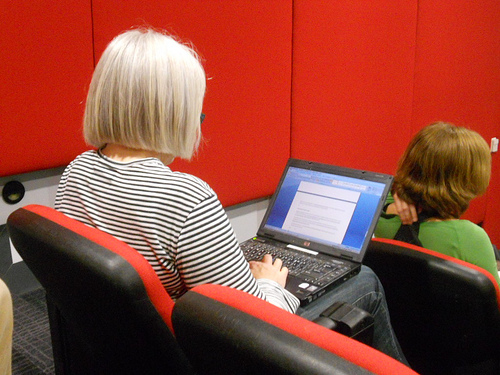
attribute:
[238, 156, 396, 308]
computer — black, opened, a laptop, on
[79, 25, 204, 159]
hair — gray, white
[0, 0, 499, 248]
wall — orange, red, padded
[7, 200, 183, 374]
seat — black, orange, red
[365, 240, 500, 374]
back — black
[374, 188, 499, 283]
shirt — green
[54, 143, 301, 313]
shirt — black, striped, white, long sleeved, stripped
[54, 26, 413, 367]
woman — sitting down, sitting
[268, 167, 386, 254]
screen — on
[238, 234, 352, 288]
keyboard — of laptop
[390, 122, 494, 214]
hair — red, blonde, brown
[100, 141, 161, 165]
neck — of woman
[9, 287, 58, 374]
floor — of room